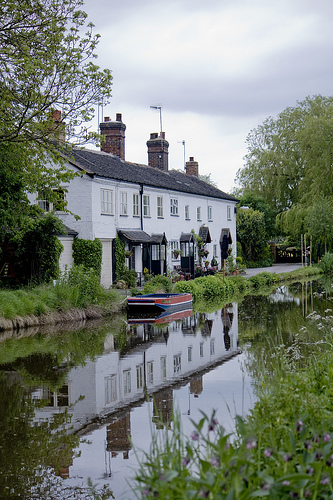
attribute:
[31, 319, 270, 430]
water — clear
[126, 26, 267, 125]
sky — cloudy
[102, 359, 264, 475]
water — clear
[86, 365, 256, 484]
water — clear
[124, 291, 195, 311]
boat — red, white , blue 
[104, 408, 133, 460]
chimney — brown 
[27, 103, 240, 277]
building — white 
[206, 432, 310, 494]
plant — tall 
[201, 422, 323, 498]
flowers — purple 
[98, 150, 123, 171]
tiles — dark 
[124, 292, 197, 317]
boat — red, white , blue 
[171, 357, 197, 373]
water — small 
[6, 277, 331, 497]
water — clear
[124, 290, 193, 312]
boat — small 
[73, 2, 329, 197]
sky — cloudy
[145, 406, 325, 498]
flowers — purple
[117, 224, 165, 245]
overhang — flat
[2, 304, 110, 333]
grass — dead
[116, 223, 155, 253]
awning — porch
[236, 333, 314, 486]
flowers — purple 